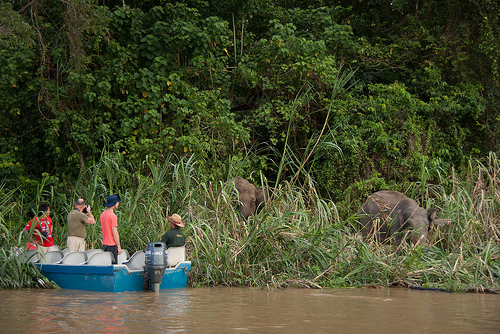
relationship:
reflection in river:
[76, 294, 159, 317] [0, 271, 500, 334]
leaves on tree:
[131, 81, 169, 126] [79, 23, 295, 187]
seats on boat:
[49, 245, 118, 264] [25, 262, 193, 291]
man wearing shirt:
[94, 188, 130, 262] [99, 212, 113, 245]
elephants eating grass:
[200, 180, 442, 244] [196, 219, 466, 279]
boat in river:
[25, 262, 193, 291] [0, 271, 500, 334]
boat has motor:
[25, 262, 193, 291] [144, 240, 171, 280]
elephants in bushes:
[200, 180, 442, 244] [114, 100, 499, 255]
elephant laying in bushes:
[348, 186, 453, 275] [114, 100, 499, 255]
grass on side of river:
[196, 219, 466, 279] [14, 270, 500, 333]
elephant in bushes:
[348, 186, 453, 275] [114, 100, 499, 255]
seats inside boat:
[49, 245, 118, 264] [25, 262, 193, 291]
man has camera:
[65, 197, 99, 262] [83, 202, 91, 213]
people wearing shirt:
[24, 201, 60, 262] [99, 212, 113, 245]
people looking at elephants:
[18, 201, 197, 256] [200, 180, 442, 244]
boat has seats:
[25, 262, 193, 291] [49, 245, 118, 264]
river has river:
[14, 270, 500, 333] [0, 271, 500, 334]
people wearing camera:
[24, 201, 60, 262] [41, 227, 51, 243]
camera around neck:
[41, 227, 51, 243] [35, 217, 47, 221]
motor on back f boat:
[144, 240, 171, 280] [25, 262, 193, 291]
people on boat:
[18, 201, 197, 256] [25, 262, 193, 291]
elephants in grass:
[200, 180, 442, 244] [196, 219, 466, 279]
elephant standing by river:
[348, 186, 453, 275] [14, 270, 500, 333]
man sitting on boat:
[156, 211, 188, 253] [25, 262, 193, 291]